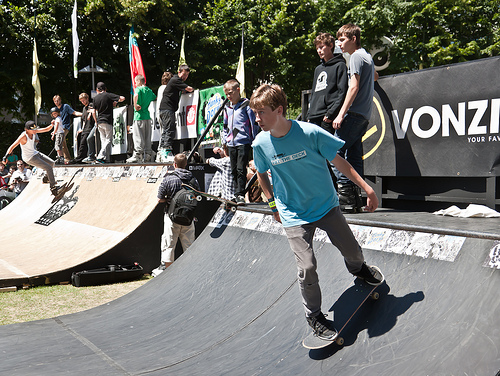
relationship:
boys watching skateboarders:
[302, 38, 389, 94] [12, 118, 75, 207]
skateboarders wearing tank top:
[12, 118, 75, 207] [21, 135, 40, 165]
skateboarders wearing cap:
[12, 118, 75, 207] [24, 119, 37, 133]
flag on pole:
[60, 16, 93, 68] [71, 79, 82, 97]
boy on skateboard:
[219, 84, 381, 303] [316, 282, 373, 337]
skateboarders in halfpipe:
[12, 118, 75, 207] [70, 168, 151, 239]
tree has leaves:
[252, 16, 306, 81] [272, 45, 284, 55]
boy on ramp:
[219, 84, 381, 303] [150, 263, 249, 347]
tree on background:
[252, 16, 306, 81] [19, 11, 437, 63]